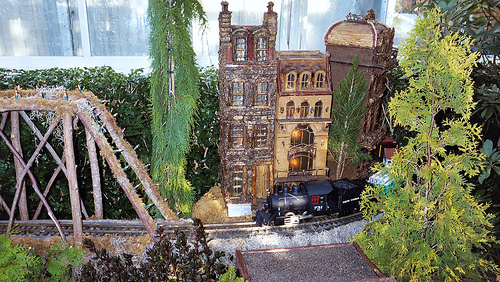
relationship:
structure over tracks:
[2, 85, 183, 250] [0, 208, 370, 242]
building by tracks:
[218, 1, 396, 215] [1, 215, 246, 244]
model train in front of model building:
[251, 175, 372, 227] [332, 5, 394, 176]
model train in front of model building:
[251, 175, 372, 227] [277, 49, 334, 175]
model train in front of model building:
[251, 175, 372, 227] [215, 4, 281, 211]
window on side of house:
[316, 74, 322, 86] [275, 50, 330, 180]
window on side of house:
[299, 72, 309, 86] [275, 50, 330, 180]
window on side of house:
[286, 72, 294, 89] [275, 50, 330, 180]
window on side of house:
[286, 101, 296, 117] [275, 50, 330, 180]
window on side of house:
[301, 101, 308, 115] [275, 50, 330, 180]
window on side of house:
[314, 100, 324, 118] [275, 50, 330, 180]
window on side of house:
[286, 101, 296, 117] [216, 1, 398, 207]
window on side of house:
[233, 32, 248, 64] [218, 3, 279, 201]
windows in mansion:
[274, 61, 329, 96] [217, 0, 400, 210]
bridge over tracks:
[0, 83, 175, 246] [5, 209, 366, 239]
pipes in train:
[369, 160, 399, 184] [244, 172, 398, 230]